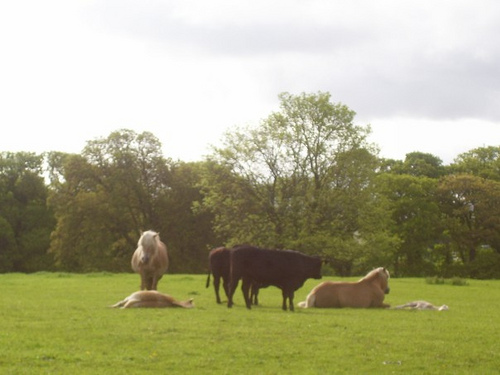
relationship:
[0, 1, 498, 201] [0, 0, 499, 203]
clouds in sky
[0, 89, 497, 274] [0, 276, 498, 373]
trees line edge of field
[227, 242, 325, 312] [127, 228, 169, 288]
cow in field horse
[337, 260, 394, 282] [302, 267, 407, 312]
mane of horse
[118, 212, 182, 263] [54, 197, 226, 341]
mane of horse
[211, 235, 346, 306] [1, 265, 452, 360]
animals in field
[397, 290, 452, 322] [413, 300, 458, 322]
horse lying on its side